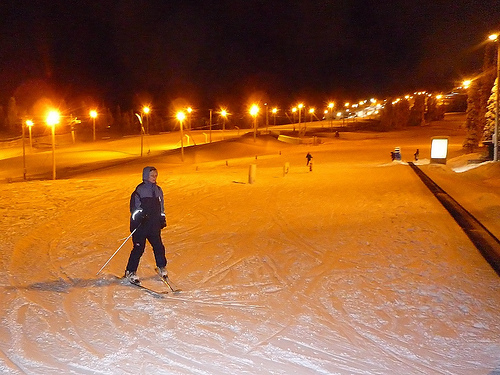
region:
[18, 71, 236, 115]
lights are on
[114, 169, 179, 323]
woman skiing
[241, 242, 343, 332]
ski marks in the snow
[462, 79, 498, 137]
snow on the trees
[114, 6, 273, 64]
time is night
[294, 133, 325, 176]
person in the snow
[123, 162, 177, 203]
woman has her hood up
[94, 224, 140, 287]
woman is holding a ski pole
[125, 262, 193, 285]
woman has snow on her boots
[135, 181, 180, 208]
woman's jacket is two colors of blue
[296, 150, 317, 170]
Person running in the distance.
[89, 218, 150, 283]
Ski stick in person's hand.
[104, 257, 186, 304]
Person's ski's attached to their boots.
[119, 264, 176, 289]
White ski boots attached to ski's.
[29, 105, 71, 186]
Slope light at bottom of slope.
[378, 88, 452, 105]
Slope lights at top of slope.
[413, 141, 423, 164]
Person in the distance with dark jacket.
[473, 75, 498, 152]
Pine tree covered in snow.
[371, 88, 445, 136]
Trees lining the top half of the slope.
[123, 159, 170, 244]
Purple and black ski jacket.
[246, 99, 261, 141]
a light that is turned on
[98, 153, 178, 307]
a woman that is skiing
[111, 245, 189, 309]
a pair of white skis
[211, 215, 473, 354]
white snow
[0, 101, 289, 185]
a ski track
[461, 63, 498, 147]
tress with snow on them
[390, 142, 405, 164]
two blue trash cans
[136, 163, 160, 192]
a woman skiers head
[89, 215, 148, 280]
a shinny chrome ski pole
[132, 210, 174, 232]
a pair of black gloves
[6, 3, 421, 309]
Skiing at night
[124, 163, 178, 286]
Gray and black ski outfit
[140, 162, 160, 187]
Her hood is up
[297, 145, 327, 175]
Skier in the distance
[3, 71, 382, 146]
Long row of lights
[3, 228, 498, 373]
Lots of criss-cross ski tracks in the snow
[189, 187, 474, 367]
Snow is packed down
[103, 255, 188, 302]
Skis pointed in to slow down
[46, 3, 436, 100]
Very dark sky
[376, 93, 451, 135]
Row of pine trees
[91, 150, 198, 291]
the man is skiing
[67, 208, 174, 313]
man holding ski poles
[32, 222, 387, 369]
tracks are in snow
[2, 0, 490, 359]
scene takes place at night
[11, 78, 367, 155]
all the street lights are on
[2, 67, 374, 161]
the lights are orange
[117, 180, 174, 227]
man's jacket is black and gray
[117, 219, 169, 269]
man's pants are black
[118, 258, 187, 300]
ski shoes are white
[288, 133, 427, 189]
people skiing in background